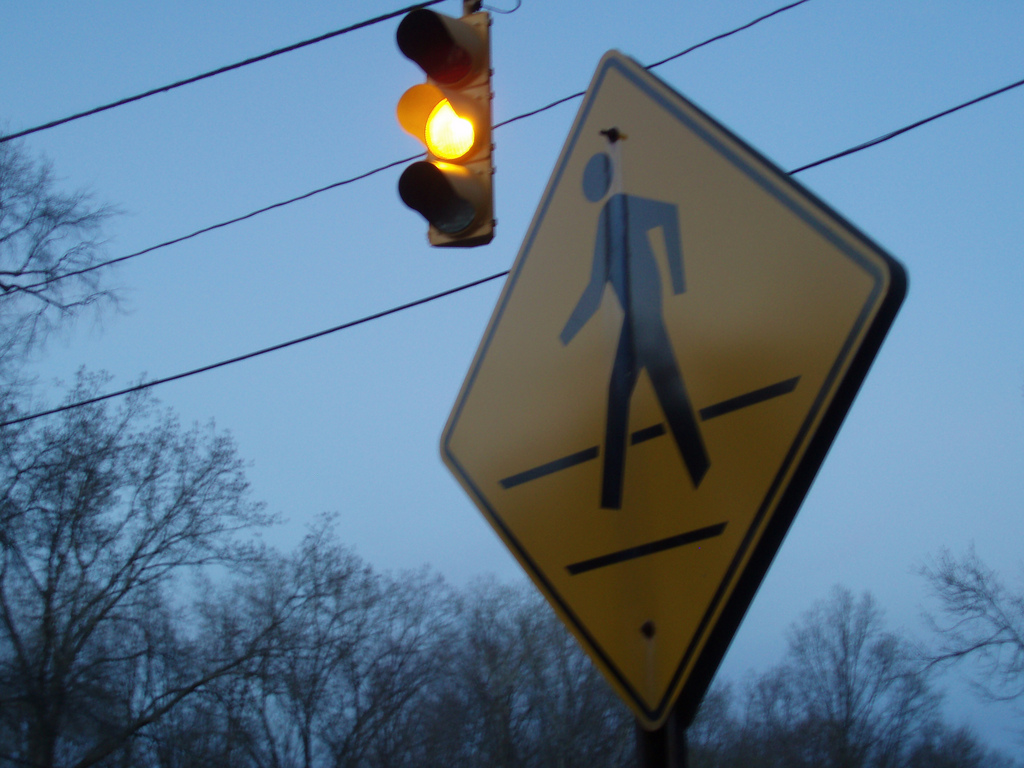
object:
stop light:
[393, 4, 497, 247]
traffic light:
[392, 80, 493, 166]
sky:
[2, 0, 1021, 768]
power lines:
[2, 0, 1024, 432]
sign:
[437, 46, 912, 728]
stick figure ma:
[558, 155, 713, 513]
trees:
[0, 140, 1021, 766]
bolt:
[595, 123, 637, 144]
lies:
[493, 376, 797, 582]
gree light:
[397, 160, 488, 236]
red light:
[388, 8, 490, 89]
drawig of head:
[577, 152, 614, 206]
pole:
[631, 714, 690, 768]